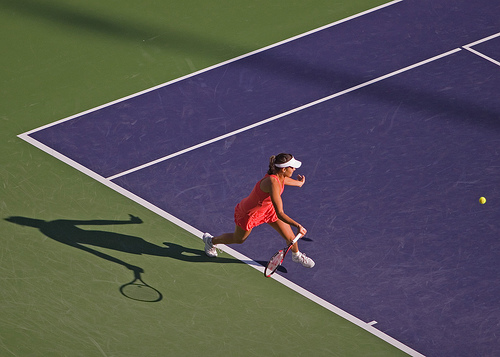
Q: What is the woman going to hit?
A: The tennis ball.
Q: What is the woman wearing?
A: Tennis dress.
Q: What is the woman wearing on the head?
A: Sun visor.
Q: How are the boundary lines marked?
A: White paint.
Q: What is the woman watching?
A: The tennis ball.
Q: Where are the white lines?
A: Tennis court.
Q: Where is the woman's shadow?
A: Behind the woman.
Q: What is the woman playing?
A: Tennis.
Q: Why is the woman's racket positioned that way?
A: She's about to hit the ball.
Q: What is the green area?
A: Out of bounds.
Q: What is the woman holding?
A: Tennis racket.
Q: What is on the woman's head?
A: Visor.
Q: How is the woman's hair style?
A: Ponytail.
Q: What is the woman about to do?
A: Hit the ball.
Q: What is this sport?
A: Tennis.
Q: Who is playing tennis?
A: A woman.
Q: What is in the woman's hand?
A: Tennis racket.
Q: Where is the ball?
A: In the air.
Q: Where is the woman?
A: On a tennis court.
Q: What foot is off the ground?
A: Woman's left foot.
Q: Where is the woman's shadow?
A: Green part of the tennis court.